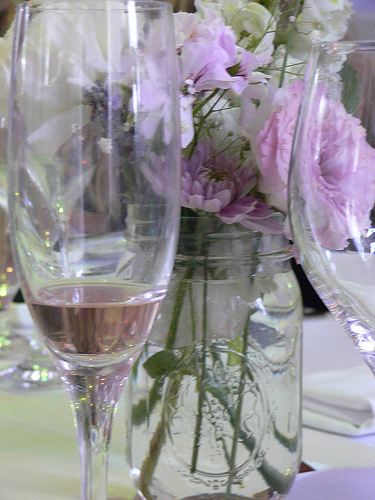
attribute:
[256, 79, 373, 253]
flower — violet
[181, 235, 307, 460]
jar — clear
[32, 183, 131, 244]
wine glass — clear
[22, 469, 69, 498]
table — white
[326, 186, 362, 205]
wine glass — clear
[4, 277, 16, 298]
wine glass — clear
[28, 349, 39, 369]
wine glass — clear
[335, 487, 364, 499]
tablecloth — white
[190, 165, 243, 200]
flower — purple, violet, pretty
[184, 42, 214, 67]
flower — purple, violet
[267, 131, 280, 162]
flower — purple, violet, pretty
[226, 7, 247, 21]
flower — white, pretty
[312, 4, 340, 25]
flower — white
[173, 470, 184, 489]
water — clear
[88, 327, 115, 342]
wine — purple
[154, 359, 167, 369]
leaf — green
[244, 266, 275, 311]
jar — clear, glass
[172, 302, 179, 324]
stem — green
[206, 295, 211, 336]
stem — green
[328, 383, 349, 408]
napkin — white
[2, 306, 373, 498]
table — cloth